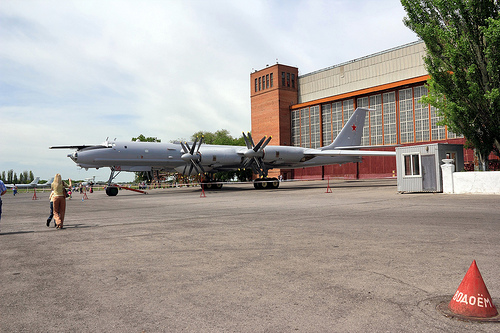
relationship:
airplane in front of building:
[51, 104, 396, 189] [251, 34, 499, 184]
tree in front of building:
[399, 2, 500, 173] [251, 34, 499, 184]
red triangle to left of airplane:
[198, 189, 208, 201] [51, 104, 396, 189]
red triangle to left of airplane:
[324, 187, 333, 194] [51, 104, 396, 189]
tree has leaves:
[399, 2, 500, 173] [402, 1, 499, 154]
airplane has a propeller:
[51, 104, 396, 189] [177, 139, 206, 179]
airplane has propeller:
[51, 104, 396, 189] [239, 132, 273, 171]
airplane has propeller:
[51, 104, 396, 189] [61, 151, 81, 166]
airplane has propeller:
[51, 104, 396, 189] [139, 171, 156, 183]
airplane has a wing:
[51, 104, 396, 189] [304, 146, 400, 162]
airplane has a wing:
[51, 104, 396, 189] [44, 141, 111, 155]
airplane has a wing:
[51, 104, 396, 189] [324, 107, 377, 147]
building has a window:
[251, 34, 499, 184] [332, 101, 343, 144]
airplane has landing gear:
[51, 104, 396, 189] [105, 173, 120, 196]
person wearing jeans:
[44, 189, 53, 230] [45, 203, 53, 229]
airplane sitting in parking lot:
[51, 104, 396, 189] [2, 186, 499, 330]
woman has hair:
[48, 174, 68, 230] [52, 177, 67, 196]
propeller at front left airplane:
[177, 139, 206, 179] [51, 104, 396, 189]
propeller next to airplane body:
[239, 132, 273, 171] [81, 143, 357, 171]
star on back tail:
[350, 123, 359, 135] [327, 104, 372, 152]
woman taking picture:
[48, 174, 68, 230] [36, 88, 456, 205]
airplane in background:
[5, 176, 42, 196] [0, 132, 252, 201]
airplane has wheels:
[51, 104, 396, 189] [197, 180, 227, 191]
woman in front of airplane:
[48, 174, 68, 230] [51, 104, 396, 189]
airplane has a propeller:
[51, 104, 396, 189] [139, 171, 156, 183]